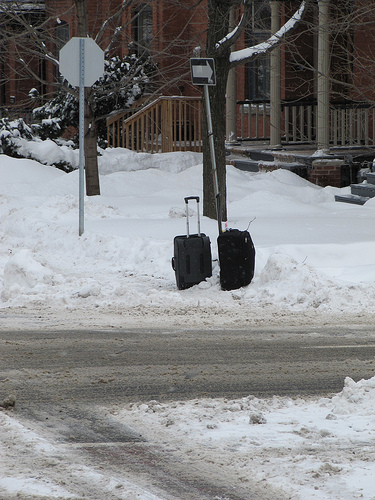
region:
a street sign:
[181, 55, 222, 85]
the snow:
[268, 434, 322, 493]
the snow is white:
[338, 404, 369, 429]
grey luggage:
[177, 236, 213, 289]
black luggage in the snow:
[217, 234, 256, 287]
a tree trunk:
[85, 138, 107, 192]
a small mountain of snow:
[251, 190, 285, 205]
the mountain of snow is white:
[129, 171, 161, 190]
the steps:
[261, 151, 290, 167]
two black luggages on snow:
[171, 191, 256, 294]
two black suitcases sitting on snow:
[170, 189, 258, 292]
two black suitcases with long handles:
[169, 190, 261, 290]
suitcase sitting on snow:
[168, 193, 215, 291]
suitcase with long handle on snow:
[170, 195, 215, 289]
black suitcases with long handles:
[169, 191, 258, 290]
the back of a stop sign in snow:
[56, 32, 107, 236]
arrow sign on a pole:
[188, 56, 223, 234]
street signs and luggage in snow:
[56, 34, 259, 291]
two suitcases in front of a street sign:
[169, 53, 261, 290]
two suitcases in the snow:
[173, 190, 257, 288]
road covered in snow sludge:
[5, 314, 371, 396]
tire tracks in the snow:
[33, 402, 233, 498]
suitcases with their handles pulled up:
[175, 194, 254, 289]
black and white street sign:
[187, 59, 217, 84]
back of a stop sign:
[58, 35, 103, 81]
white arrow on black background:
[192, 62, 213, 80]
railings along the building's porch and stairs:
[103, 89, 368, 145]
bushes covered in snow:
[0, 113, 87, 168]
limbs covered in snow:
[228, 9, 308, 62]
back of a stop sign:
[56, 34, 106, 237]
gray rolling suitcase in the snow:
[166, 184, 212, 289]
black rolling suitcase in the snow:
[211, 192, 257, 292]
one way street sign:
[182, 54, 215, 86]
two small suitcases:
[162, 185, 261, 294]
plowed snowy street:
[2, 306, 373, 431]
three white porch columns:
[226, 2, 334, 159]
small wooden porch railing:
[102, 92, 210, 156]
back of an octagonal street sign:
[54, 33, 105, 92]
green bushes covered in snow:
[4, 55, 155, 192]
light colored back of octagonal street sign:
[55, 35, 105, 88]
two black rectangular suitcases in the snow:
[167, 192, 255, 294]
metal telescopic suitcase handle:
[183, 194, 203, 235]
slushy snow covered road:
[10, 308, 372, 413]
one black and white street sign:
[187, 51, 230, 208]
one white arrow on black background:
[186, 55, 219, 87]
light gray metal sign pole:
[77, 88, 87, 238]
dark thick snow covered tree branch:
[232, 4, 308, 68]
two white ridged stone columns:
[263, 2, 333, 154]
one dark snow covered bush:
[5, 120, 76, 174]